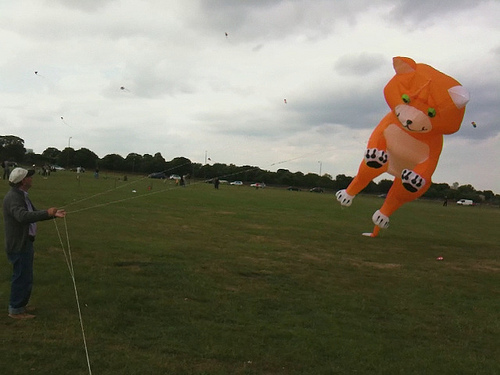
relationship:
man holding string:
[5, 164, 65, 319] [53, 127, 325, 372]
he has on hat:
[5, 164, 65, 319] [8, 163, 35, 188]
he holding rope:
[5, 164, 65, 319] [53, 127, 325, 372]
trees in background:
[0, 131, 499, 205] [1, 112, 496, 214]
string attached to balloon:
[53, 127, 325, 372] [332, 36, 471, 242]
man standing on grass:
[5, 164, 65, 319] [0, 162, 499, 373]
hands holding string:
[47, 201, 66, 220] [53, 127, 325, 372]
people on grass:
[1, 156, 263, 192] [0, 162, 499, 373]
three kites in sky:
[29, 66, 128, 122] [0, 2, 499, 194]